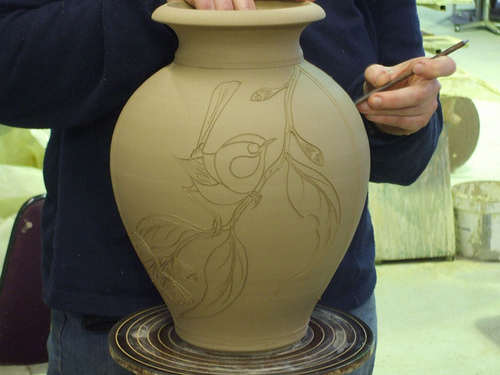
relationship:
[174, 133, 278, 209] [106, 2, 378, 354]
bird etched into pot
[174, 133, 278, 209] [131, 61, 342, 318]
bird on tree branch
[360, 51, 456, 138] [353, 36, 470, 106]
hand holding etching tool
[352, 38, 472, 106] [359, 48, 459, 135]
tool in hand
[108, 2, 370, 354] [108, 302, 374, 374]
pot on a table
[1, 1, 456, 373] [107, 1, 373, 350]
man designing vase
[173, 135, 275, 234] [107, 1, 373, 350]
bird on a vase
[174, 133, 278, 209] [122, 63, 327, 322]
bird standing on a branch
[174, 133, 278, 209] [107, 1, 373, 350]
bird etched into vase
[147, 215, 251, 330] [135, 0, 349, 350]
leaves etched into a vase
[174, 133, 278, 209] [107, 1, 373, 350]
bird etched into a vase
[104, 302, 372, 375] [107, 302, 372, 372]
potter's wheel on top of potter's wheel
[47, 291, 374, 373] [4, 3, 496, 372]
jeans in photo